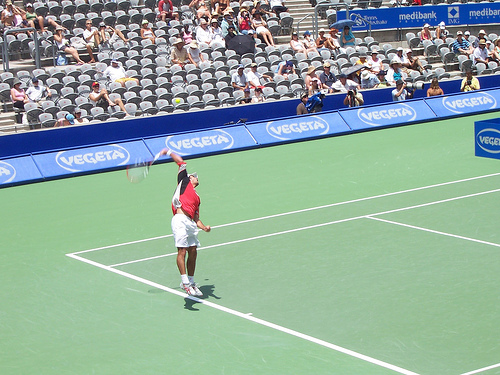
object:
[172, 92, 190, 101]
chair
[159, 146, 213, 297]
tennis player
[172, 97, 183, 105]
ball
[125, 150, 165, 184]
tennis racket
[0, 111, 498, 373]
tennis court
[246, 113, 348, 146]
advertisement sign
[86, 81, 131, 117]
spectator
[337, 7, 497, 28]
advertisement sign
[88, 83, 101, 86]
hat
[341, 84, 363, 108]
man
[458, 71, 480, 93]
man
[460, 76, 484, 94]
shirt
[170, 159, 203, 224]
shirt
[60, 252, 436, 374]
line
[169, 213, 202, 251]
shorts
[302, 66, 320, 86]
spectator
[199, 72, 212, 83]
chair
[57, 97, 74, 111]
chair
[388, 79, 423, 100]
camera man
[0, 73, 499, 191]
wall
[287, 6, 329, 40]
stairs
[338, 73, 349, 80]
hat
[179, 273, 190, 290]
socks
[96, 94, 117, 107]
legs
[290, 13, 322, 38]
rail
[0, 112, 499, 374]
court